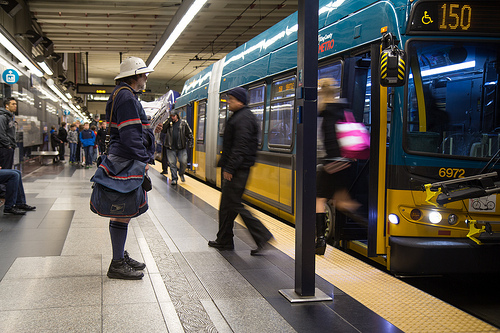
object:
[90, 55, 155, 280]
mail man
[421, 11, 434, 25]
handicap sign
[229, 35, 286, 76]
roof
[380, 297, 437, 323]
ground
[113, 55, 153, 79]
hard hat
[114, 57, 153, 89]
head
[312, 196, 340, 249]
wheel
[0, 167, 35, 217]
person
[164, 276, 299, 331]
floor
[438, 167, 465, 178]
6972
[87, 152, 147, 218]
bag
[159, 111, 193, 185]
man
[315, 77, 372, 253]
passenger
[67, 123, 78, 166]
child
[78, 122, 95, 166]
child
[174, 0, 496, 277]
bus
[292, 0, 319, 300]
pillar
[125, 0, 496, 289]
train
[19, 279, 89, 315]
floor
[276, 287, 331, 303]
base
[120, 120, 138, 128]
stripe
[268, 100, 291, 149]
windows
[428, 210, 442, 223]
shining light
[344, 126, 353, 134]
yellow pink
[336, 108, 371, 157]
bag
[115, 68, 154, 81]
brim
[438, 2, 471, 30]
numbers 150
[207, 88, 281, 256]
man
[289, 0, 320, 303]
beam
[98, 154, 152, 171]
waist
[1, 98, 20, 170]
man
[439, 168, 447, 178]
numbers